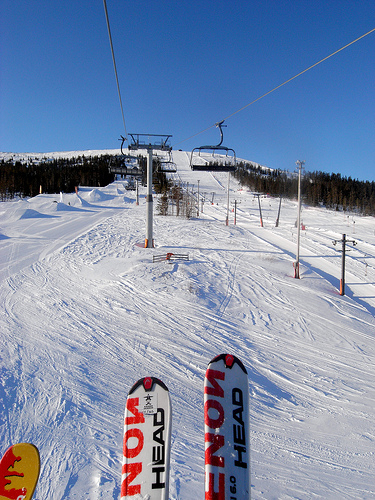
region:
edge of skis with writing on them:
[118, 351, 258, 499]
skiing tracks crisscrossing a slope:
[22, 278, 127, 378]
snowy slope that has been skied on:
[37, 287, 124, 369]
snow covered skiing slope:
[8, 197, 371, 341]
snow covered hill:
[2, 150, 369, 326]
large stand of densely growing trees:
[0, 152, 127, 197]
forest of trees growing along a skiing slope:
[235, 154, 372, 214]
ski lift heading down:
[186, 143, 241, 170]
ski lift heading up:
[105, 151, 140, 174]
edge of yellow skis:
[0, 440, 53, 498]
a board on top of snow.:
[200, 349, 254, 499]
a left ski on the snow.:
[111, 372, 184, 498]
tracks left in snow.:
[85, 288, 147, 342]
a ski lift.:
[187, 115, 240, 170]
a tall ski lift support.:
[113, 128, 180, 248]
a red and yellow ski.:
[0, 438, 51, 498]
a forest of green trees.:
[203, 159, 373, 219]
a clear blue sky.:
[0, 0, 373, 183]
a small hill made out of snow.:
[85, 182, 116, 211]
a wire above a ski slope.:
[169, 27, 374, 149]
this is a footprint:
[191, 230, 250, 308]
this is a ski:
[174, 407, 255, 491]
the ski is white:
[188, 292, 241, 482]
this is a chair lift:
[187, 170, 217, 172]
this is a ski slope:
[74, 122, 154, 233]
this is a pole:
[284, 186, 302, 201]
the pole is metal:
[265, 225, 329, 236]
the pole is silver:
[291, 185, 312, 204]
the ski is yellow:
[25, 457, 65, 475]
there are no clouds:
[191, 118, 213, 134]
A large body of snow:
[46, 270, 167, 348]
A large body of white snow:
[70, 272, 186, 337]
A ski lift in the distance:
[186, 124, 249, 178]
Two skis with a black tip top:
[101, 354, 257, 499]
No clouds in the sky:
[132, 30, 213, 98]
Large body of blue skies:
[123, 24, 243, 82]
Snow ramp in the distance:
[90, 189, 109, 204]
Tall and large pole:
[144, 144, 157, 252]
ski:
[190, 344, 251, 492]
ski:
[102, 376, 181, 498]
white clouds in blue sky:
[6, 53, 46, 105]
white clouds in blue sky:
[97, 43, 145, 70]